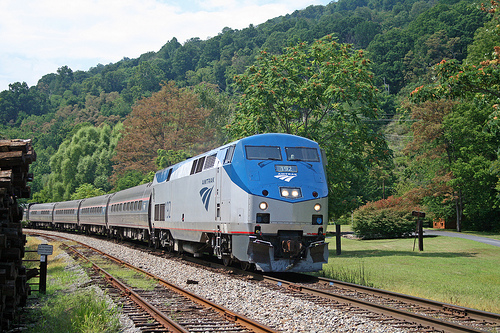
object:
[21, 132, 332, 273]
train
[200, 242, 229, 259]
engine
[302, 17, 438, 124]
trees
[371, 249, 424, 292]
grass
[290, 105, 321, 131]
branches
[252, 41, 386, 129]
tree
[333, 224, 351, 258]
trunk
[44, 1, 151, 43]
clouds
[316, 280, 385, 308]
track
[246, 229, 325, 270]
train engine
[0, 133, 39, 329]
logs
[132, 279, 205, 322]
train track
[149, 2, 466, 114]
hillside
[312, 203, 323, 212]
light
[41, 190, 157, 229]
passenger cars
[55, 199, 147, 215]
windows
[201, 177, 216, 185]
brand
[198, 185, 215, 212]
logo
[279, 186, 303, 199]
headlights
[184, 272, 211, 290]
gravel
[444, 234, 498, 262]
field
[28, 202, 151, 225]
cars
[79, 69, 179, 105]
forest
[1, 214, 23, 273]
wood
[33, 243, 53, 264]
sign post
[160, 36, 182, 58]
background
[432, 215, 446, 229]
object